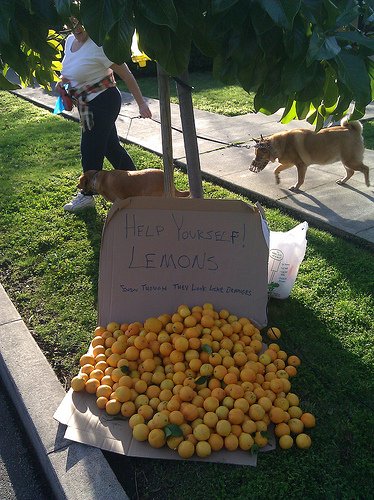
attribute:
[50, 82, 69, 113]
bag — red, small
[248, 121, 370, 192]
dog — brown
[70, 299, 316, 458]
bunch — large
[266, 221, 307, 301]
plastic bag — white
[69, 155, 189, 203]
dog — small, brown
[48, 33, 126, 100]
shirt — white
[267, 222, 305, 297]
plastic bag — white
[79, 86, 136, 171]
pants — blue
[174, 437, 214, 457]
lemons — small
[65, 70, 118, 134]
shirt — plaid